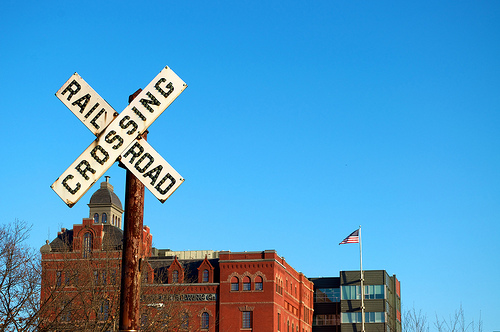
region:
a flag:
[326, 218, 375, 263]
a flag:
[311, 217, 398, 314]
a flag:
[336, 196, 370, 273]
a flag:
[322, 207, 402, 277]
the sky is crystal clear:
[210, 80, 320, 187]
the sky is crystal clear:
[281, 145, 411, 255]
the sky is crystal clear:
[287, 125, 349, 195]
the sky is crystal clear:
[290, 150, 320, 176]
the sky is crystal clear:
[290, 125, 330, 170]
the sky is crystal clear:
[295, 175, 345, 200]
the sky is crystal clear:
[255, 146, 295, 176]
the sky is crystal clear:
[261, 90, 317, 141]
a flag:
[315, 170, 410, 297]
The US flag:
[295, 205, 419, 253]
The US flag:
[330, 202, 390, 329]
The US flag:
[322, 231, 346, 312]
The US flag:
[301, 195, 366, 323]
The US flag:
[361, 244, 411, 322]